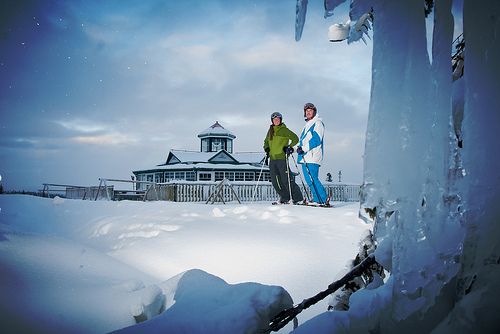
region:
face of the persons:
[253, 77, 343, 142]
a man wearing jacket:
[293, 118, 350, 175]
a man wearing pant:
[302, 164, 349, 205]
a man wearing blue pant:
[306, 158, 335, 208]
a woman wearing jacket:
[252, 122, 304, 159]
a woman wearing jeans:
[261, 145, 296, 207]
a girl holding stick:
[226, 154, 302, 212]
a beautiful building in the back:
[111, 113, 262, 195]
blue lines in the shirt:
[311, 134, 336, 156]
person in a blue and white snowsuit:
[294, 98, 336, 215]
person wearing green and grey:
[261, 103, 303, 212]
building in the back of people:
[125, 111, 296, 211]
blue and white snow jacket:
[292, 114, 329, 167]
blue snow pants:
[299, 160, 332, 207]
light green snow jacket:
[262, 123, 303, 163]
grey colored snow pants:
[268, 153, 300, 205]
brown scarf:
[266, 121, 286, 142]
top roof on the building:
[195, 116, 236, 140]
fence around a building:
[160, 176, 370, 206]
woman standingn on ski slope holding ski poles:
[298, 96, 335, 220]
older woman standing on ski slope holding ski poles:
[246, 103, 304, 214]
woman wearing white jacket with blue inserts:
[293, 113, 329, 165]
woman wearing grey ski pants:
[266, 156, 298, 207]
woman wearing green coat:
[262, 118, 302, 159]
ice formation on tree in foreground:
[276, 0, 491, 325]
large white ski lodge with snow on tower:
[125, 103, 356, 206]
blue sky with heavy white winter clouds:
[11, 0, 373, 186]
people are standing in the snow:
[249, 92, 336, 200]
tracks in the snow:
[207, 185, 288, 233]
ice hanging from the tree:
[371, 42, 449, 237]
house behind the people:
[139, 108, 243, 202]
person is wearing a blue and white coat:
[291, 116, 321, 164]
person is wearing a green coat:
[260, 122, 299, 161]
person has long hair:
[267, 125, 275, 143]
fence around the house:
[153, 179, 263, 204]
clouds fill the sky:
[121, 15, 216, 97]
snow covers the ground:
[27, 190, 181, 289]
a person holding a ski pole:
[246, 149, 271, 202]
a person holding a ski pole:
[279, 147, 293, 197]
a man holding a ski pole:
[299, 146, 325, 204]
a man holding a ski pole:
[290, 144, 310, 207]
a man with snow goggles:
[300, 102, 315, 109]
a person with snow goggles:
[268, 111, 284, 119]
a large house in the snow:
[129, 116, 286, 200]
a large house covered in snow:
[126, 114, 293, 201]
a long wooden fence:
[35, 176, 370, 208]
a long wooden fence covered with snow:
[63, 180, 367, 202]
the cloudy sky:
[7, 2, 377, 180]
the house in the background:
[113, 115, 269, 207]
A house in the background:
[125, 106, 280, 201]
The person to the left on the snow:
[255, 100, 306, 206]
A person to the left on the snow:
[255, 108, 307, 206]